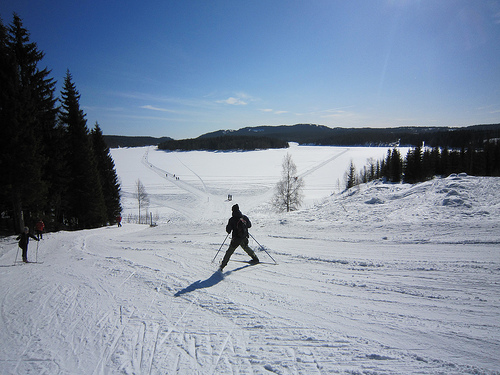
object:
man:
[216, 203, 260, 268]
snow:
[0, 144, 500, 374]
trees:
[58, 67, 111, 232]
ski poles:
[36, 241, 39, 263]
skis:
[230, 259, 280, 265]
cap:
[232, 203, 240, 211]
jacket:
[226, 215, 252, 239]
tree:
[271, 151, 307, 214]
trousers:
[221, 238, 260, 267]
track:
[279, 244, 500, 374]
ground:
[0, 266, 500, 375]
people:
[115, 214, 123, 227]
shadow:
[174, 262, 262, 298]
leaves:
[78, 187, 93, 195]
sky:
[0, 0, 500, 142]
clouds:
[217, 92, 250, 109]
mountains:
[93, 123, 499, 148]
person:
[15, 227, 40, 263]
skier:
[33, 218, 45, 241]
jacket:
[35, 222, 45, 231]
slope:
[0, 211, 500, 375]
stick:
[211, 234, 230, 262]